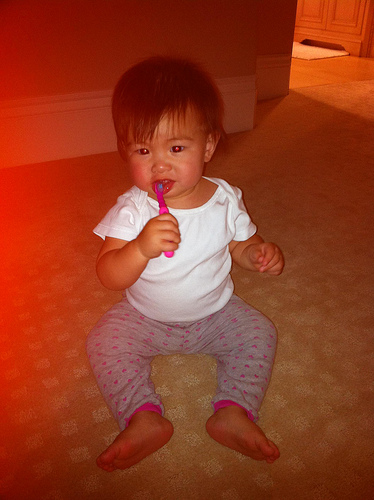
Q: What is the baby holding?
A: Toothbrush.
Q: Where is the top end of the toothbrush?
A: In the baby's mouth.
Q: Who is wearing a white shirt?
A: Baby.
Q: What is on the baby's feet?
A: Nothing.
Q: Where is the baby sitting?
A: Floor.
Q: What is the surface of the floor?
A: Carpet.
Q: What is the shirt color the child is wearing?
A: White.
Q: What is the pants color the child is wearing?
A: Gray with pink hearts.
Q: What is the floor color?
A: Brown with a white square design.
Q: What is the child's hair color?
A: Brown.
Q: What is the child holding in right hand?
A: Toothbrush.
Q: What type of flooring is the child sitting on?
A: Carpet.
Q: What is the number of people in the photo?
A: One.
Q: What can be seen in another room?
A: A brown wardrobe dresser.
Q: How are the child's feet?
A: Barefoot.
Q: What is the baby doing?
A: Sitting on carpet with a toothbrush.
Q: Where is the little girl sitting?
A: On a tile floor.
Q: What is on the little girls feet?
A: The little girls feet a bare.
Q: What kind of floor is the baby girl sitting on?
A: The baby girl is sitting on a tile floor.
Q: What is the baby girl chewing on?
A: The baby girl is chewing a spoon.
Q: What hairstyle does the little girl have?
A: The little girl has a short hair style.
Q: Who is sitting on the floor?
A: Baby.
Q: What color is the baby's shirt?
A: White.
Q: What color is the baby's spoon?
A: Pink.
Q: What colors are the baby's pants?
A: Pink, grey.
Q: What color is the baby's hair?
A: Black.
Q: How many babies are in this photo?
A: One.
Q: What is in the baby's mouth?
A: Spoon.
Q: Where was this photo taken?
A: Near baby.